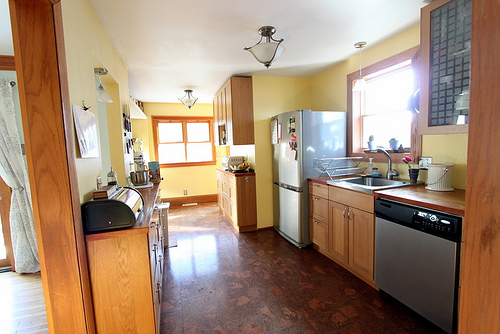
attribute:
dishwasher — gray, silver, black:
[381, 220, 446, 304]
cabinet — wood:
[323, 210, 365, 263]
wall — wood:
[257, 85, 270, 100]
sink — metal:
[345, 176, 391, 189]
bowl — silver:
[132, 170, 149, 183]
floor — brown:
[237, 246, 259, 281]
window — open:
[158, 117, 213, 162]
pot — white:
[426, 166, 453, 189]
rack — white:
[335, 163, 353, 175]